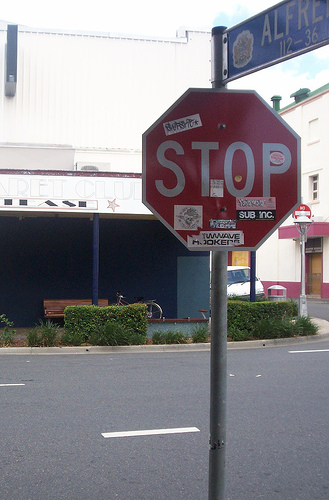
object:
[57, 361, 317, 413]
pavement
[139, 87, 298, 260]
sign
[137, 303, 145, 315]
bush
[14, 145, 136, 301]
building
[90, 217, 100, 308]
pole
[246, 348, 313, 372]
by a road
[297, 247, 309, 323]
light pole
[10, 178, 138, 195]
name of the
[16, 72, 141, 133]
building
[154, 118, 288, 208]
stickers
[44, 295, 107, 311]
bench against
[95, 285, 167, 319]
there is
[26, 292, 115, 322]
to the bench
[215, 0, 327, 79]
street sign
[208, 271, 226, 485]
pole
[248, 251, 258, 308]
there is a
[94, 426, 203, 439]
line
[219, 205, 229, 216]
art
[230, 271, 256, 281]
window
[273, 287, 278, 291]
part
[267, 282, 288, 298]
litter bin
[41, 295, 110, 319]
bench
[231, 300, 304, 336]
hedge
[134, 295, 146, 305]
bicycle sitting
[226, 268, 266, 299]
van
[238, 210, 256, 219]
writing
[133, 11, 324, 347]
city street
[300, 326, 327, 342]
curb separates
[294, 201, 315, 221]
do not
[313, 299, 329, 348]
corner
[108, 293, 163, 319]
bicycle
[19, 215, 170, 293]
under building